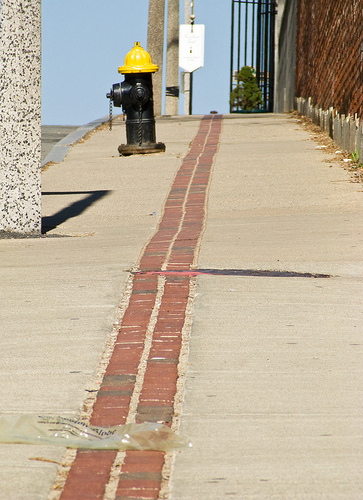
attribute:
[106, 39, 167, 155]
hydrant — black, yellow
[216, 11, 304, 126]
fence — black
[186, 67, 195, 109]
pole — black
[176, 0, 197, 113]
poles — wooden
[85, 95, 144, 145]
chains — black 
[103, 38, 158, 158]
hydrant — black, yellow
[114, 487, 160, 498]
brick — red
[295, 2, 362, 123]
wall — brick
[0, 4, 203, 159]
poles — grey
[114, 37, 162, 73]
top — yellow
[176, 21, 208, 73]
sign — white